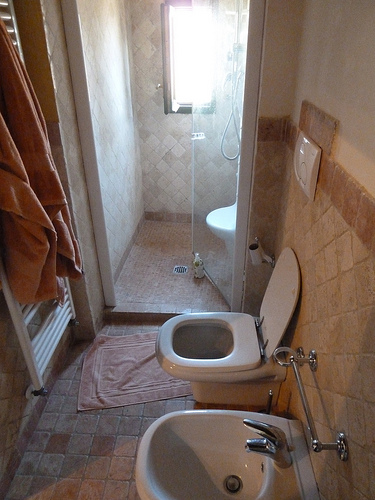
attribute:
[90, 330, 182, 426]
towel — hanging up, pink, hanging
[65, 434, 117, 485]
floor — light colored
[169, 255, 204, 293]
drain — shower drain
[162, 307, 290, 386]
toilet — seat up, shown seat up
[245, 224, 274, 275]
toilet paper — almost done, almost gone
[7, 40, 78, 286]
other towel — on drying rack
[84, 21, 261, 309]
shower — open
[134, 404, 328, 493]
sink — empty, oval, white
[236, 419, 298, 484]
faucet — metal, silver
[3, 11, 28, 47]
towel rack — metal, empty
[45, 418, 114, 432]
tiles — multi colored